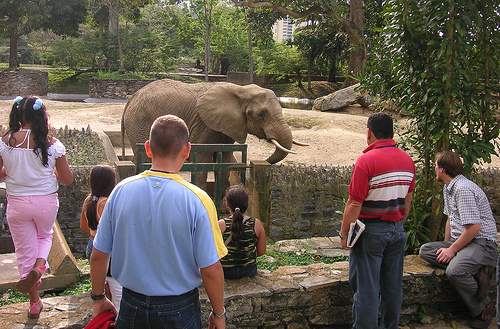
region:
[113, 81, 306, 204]
elephant in enclosure space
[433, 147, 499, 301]
man sitting on concrete near elephant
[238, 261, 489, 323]
concrete wall by enclosure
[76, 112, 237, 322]
man standing near elephant exhibit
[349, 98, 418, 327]
man standing near man sitting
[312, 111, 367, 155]
ground area near elephant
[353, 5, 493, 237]
tree near elephant enclosure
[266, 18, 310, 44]
building behind elephant exhibit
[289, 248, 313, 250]
flowers in green area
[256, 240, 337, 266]
green area near elephant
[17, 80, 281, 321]
The children are looking at the elephant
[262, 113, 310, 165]
The elephant has two tusks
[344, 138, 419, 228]
The man is wearing a red shirt with stripes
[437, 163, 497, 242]
The man is wearing a checkered shirt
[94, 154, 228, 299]
The boy is wearing a blue and yellow shirt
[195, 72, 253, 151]
The elephant's right ear lobe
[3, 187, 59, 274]
The girl is wearing pink pants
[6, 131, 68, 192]
The girl is wearing a white blouse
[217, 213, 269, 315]
The girl sits on the rocks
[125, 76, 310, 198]
The elephant is looking forward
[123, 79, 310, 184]
The elephant is brown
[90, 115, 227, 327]
Man looking at elephant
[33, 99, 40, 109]
Hair bow is blue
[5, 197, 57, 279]
The pants are pink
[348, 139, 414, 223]
The shirt is red with stripes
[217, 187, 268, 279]
Girl is sitting down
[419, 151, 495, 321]
A guy is looking at the elephant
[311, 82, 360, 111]
A large gray rock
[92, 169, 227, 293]
Shirt is blue and yellow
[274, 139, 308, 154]
Elephant has long tusks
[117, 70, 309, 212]
an elephant in its habitat at a zoo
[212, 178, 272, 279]
a little girl watches the elephant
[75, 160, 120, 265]
a girl with long hair watches the elephant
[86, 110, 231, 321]
this guy has a buzz cut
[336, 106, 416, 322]
this guy is wearing a striped shirt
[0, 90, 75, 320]
this girl is standing on one foot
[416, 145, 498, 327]
this gentleman is wearing a gray ensemble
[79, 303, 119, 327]
buzz cut guy is carrying a backpack with red straps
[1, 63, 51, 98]
tree planters are made of stone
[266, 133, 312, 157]
the elephant has tusks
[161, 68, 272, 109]
Elephant standing in the zoo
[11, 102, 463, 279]
Lot of peoples watching the elephants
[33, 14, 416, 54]
Lot of trees with branches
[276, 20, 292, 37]
Buildings near the zoo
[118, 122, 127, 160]
Tail of the elephant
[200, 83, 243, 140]
Huge ear shaped like africa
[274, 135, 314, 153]
Tusk of the elephant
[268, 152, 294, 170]
Trunk of the elephant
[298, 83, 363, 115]
Big size stone in the dirt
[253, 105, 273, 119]
Eye of the elephant